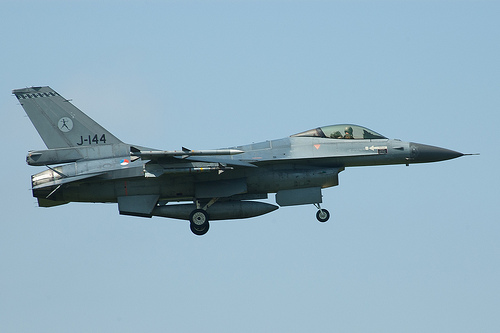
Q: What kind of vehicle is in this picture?
A: A jet.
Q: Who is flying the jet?
A: The pilot.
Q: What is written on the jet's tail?
A: J-144.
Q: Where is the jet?
A: In the sky.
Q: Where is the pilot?
A: In the cockpit.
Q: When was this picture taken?
A: Day time.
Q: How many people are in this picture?
A: One.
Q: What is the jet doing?
A: Flying.